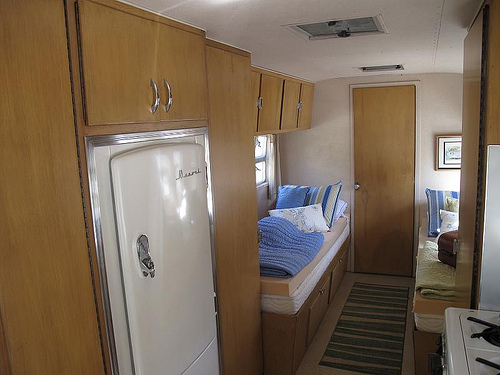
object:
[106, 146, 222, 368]
refrigerator door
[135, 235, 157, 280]
handle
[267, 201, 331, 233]
pillow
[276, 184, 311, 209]
pillow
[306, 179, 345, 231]
pillow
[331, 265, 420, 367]
floor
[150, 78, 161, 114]
handle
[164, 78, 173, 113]
handle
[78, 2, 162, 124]
cabinet door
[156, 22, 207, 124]
cabinet door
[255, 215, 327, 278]
blanket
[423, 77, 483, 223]
wall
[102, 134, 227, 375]
refrigerator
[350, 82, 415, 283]
door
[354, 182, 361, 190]
door handle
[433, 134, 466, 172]
frame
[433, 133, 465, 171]
framed painting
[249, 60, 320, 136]
cabinets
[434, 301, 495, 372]
stove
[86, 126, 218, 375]
fridge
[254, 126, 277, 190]
window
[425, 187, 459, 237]
pillows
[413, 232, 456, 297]
blanket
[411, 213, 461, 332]
bed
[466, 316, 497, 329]
burner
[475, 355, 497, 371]
burner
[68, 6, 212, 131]
cabinets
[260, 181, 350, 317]
bed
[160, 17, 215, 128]
door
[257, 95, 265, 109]
hendge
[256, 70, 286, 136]
door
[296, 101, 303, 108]
hendge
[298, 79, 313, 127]
door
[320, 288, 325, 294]
hendge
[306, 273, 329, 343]
door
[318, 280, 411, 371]
floor mat